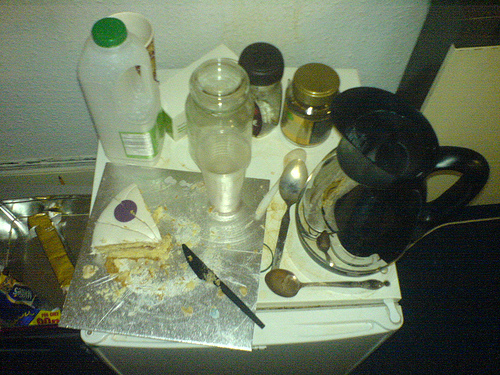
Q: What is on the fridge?
A: Spoons.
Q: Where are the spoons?
A: Next to kettle.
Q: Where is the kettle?
A: Next to spoons.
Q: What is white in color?
A: The fridge.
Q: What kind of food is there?
A: Cake.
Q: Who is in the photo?
A: No people.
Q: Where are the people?
A: None in photo.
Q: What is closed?
A: The fridge.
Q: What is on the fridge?
A: Many objects.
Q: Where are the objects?
A: On the fridge.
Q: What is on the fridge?
A: Spoon.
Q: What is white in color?
A: The cake.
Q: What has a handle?
A: The silver jug.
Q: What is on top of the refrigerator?
A: The items.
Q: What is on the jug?
A: Green cap.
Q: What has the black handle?
A: The coffee server.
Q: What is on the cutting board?
A: Knife.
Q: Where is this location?
A: Kitchen.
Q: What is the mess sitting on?
A: Refrigerator.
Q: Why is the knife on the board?
A: Cutting food.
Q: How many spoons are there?
A: Three.